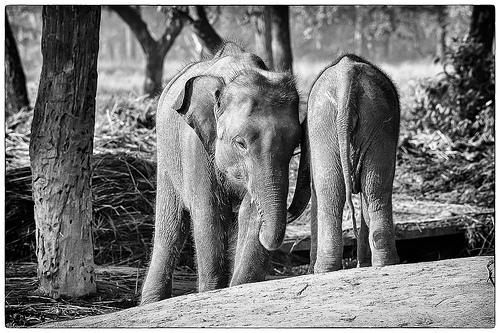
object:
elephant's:
[305, 57, 403, 269]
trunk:
[249, 155, 289, 252]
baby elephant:
[139, 39, 300, 304]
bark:
[28, 24, 96, 296]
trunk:
[24, 6, 103, 300]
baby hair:
[221, 67, 298, 114]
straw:
[0, 151, 159, 261]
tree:
[27, 4, 102, 290]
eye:
[233, 135, 248, 149]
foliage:
[391, 54, 498, 215]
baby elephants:
[300, 51, 401, 273]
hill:
[139, 265, 497, 333]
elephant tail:
[335, 86, 361, 253]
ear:
[170, 74, 219, 159]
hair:
[229, 64, 300, 103]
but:
[304, 54, 402, 176]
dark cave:
[395, 228, 468, 262]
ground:
[31, 256, 496, 329]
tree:
[462, 6, 491, 59]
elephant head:
[212, 63, 302, 251]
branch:
[105, 7, 156, 51]